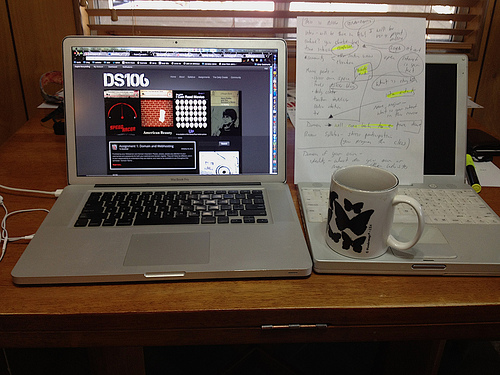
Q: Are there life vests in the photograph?
A: No, there are no life vests.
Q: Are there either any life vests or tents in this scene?
A: No, there are no life vests or tents.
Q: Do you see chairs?
A: No, there are no chairs.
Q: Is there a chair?
A: No, there are no chairs.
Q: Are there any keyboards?
A: Yes, there is a keyboard.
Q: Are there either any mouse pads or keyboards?
A: Yes, there is a keyboard.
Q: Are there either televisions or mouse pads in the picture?
A: No, there are no televisions or mouse pads.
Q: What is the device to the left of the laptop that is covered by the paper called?
A: The device is a keyboard.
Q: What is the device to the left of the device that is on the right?
A: The device is a keyboard.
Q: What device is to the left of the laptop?
A: The device is a keyboard.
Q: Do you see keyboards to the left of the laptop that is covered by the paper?
A: Yes, there is a keyboard to the left of the laptop.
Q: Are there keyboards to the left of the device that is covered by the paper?
A: Yes, there is a keyboard to the left of the laptop.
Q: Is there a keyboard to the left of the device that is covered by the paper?
A: Yes, there is a keyboard to the left of the laptop.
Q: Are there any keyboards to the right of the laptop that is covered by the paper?
A: No, the keyboard is to the left of the laptop.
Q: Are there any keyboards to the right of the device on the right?
A: No, the keyboard is to the left of the laptop.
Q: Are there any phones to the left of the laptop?
A: No, there is a keyboard to the left of the laptop.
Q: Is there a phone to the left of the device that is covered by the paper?
A: No, there is a keyboard to the left of the laptop.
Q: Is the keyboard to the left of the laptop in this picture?
A: Yes, the keyboard is to the left of the laptop.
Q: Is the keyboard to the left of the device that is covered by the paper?
A: Yes, the keyboard is to the left of the laptop.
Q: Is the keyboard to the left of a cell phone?
A: No, the keyboard is to the left of the laptop.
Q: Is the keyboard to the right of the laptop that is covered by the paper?
A: No, the keyboard is to the left of the laptop.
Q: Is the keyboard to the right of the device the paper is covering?
A: No, the keyboard is to the left of the laptop.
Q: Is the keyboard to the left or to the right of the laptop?
A: The keyboard is to the left of the laptop.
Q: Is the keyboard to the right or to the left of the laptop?
A: The keyboard is to the left of the laptop.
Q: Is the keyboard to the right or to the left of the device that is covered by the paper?
A: The keyboard is to the left of the laptop.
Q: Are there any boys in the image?
A: No, there are no boys.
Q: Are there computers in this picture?
A: Yes, there is a computer.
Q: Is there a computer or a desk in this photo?
A: Yes, there is a computer.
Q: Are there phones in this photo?
A: No, there are no phones.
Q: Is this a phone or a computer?
A: This is a computer.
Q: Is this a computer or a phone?
A: This is a computer.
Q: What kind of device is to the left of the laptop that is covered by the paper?
A: The device is a computer.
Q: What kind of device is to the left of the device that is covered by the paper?
A: The device is a computer.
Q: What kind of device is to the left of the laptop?
A: The device is a computer.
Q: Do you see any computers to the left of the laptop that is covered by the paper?
A: Yes, there is a computer to the left of the laptop computer.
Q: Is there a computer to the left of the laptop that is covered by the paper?
A: Yes, there is a computer to the left of the laptop computer.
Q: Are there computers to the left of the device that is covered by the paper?
A: Yes, there is a computer to the left of the laptop computer.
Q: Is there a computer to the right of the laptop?
A: No, the computer is to the left of the laptop.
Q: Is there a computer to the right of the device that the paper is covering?
A: No, the computer is to the left of the laptop.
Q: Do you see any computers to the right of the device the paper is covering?
A: No, the computer is to the left of the laptop.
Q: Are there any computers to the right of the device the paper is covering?
A: No, the computer is to the left of the laptop.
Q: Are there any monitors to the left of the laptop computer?
A: No, there is a computer to the left of the laptop computer.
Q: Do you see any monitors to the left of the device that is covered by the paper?
A: No, there is a computer to the left of the laptop computer.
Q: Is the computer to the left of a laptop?
A: Yes, the computer is to the left of a laptop.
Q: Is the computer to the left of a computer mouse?
A: No, the computer is to the left of a laptop.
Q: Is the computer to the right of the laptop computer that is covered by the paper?
A: No, the computer is to the left of the laptop.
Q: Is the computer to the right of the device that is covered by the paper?
A: No, the computer is to the left of the laptop.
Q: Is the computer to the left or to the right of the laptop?
A: The computer is to the left of the laptop.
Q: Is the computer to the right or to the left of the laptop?
A: The computer is to the left of the laptop.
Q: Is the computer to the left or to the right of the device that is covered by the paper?
A: The computer is to the left of the laptop.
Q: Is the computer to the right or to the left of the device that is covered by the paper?
A: The computer is to the left of the laptop.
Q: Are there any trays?
A: No, there are no trays.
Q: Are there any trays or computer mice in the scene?
A: No, there are no trays or computer mice.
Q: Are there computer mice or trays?
A: No, there are no trays or computer mice.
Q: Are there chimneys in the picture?
A: No, there are no chimneys.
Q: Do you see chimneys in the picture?
A: No, there are no chimneys.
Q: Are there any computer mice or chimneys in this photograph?
A: No, there are no chimneys or computer mice.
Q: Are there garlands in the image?
A: No, there are no garlands.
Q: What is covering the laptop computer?
A: The paper is covering the laptop computer.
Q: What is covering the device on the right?
A: The paper is covering the laptop computer.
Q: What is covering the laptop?
A: The paper is covering the laptop computer.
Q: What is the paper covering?
A: The paper is covering the laptop.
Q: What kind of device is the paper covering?
A: The paper is covering the laptop.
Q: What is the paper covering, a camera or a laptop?
A: The paper is covering a laptop.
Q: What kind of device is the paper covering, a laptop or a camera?
A: The paper is covering a laptop.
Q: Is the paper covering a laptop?
A: Yes, the paper is covering a laptop.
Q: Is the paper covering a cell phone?
A: No, the paper is covering a laptop.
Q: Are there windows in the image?
A: Yes, there is a window.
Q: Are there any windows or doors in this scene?
A: Yes, there is a window.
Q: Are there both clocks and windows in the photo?
A: No, there is a window but no clocks.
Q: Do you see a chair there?
A: No, there are no chairs.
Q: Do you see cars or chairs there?
A: No, there are no chairs or cars.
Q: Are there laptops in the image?
A: Yes, there is a laptop.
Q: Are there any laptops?
A: Yes, there is a laptop.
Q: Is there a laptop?
A: Yes, there is a laptop.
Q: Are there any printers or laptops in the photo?
A: Yes, there is a laptop.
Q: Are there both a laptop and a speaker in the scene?
A: No, there is a laptop but no speakers.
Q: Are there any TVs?
A: No, there are no tvs.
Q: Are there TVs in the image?
A: No, there are no tvs.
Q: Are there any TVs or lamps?
A: No, there are no TVs or lamps.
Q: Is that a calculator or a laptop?
A: That is a laptop.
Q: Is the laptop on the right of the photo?
A: Yes, the laptop is on the right of the image.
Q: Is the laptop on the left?
A: No, the laptop is on the right of the image.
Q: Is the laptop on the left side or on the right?
A: The laptop is on the right of the image.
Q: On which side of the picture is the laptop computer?
A: The laptop computer is on the right of the image.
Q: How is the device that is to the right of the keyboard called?
A: The device is a laptop.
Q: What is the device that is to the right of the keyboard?
A: The device is a laptop.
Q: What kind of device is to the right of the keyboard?
A: The device is a laptop.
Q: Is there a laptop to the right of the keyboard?
A: Yes, there is a laptop to the right of the keyboard.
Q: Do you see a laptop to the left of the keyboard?
A: No, the laptop is to the right of the keyboard.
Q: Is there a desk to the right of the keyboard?
A: No, there is a laptop to the right of the keyboard.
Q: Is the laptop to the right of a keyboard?
A: Yes, the laptop is to the right of a keyboard.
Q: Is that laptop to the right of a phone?
A: No, the laptop is to the right of a keyboard.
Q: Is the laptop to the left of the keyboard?
A: No, the laptop is to the right of the keyboard.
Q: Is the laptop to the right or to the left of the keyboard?
A: The laptop is to the right of the keyboard.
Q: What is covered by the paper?
A: The laptop is covered by the paper.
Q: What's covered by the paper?
A: The laptop is covered by the paper.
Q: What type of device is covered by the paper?
A: The device is a laptop.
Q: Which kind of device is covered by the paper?
A: The device is a laptop.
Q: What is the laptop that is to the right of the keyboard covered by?
A: The laptop is covered by the paper.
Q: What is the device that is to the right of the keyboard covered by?
A: The laptop is covered by the paper.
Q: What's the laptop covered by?
A: The laptop is covered by the paper.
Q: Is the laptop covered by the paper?
A: Yes, the laptop is covered by the paper.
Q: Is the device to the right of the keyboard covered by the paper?
A: Yes, the laptop is covered by the paper.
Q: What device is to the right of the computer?
A: The device is a laptop.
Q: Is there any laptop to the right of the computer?
A: Yes, there is a laptop to the right of the computer.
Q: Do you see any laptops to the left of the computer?
A: No, the laptop is to the right of the computer.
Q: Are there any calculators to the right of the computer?
A: No, there is a laptop to the right of the computer.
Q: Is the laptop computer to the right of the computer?
A: Yes, the laptop computer is to the right of the computer.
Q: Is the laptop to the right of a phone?
A: No, the laptop is to the right of the computer.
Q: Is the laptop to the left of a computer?
A: No, the laptop is to the right of a computer.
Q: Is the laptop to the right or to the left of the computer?
A: The laptop is to the right of the computer.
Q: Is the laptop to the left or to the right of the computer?
A: The laptop is to the right of the computer.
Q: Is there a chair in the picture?
A: No, there are no chairs.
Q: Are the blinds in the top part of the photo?
A: Yes, the blinds are in the top of the image.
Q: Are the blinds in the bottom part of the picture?
A: No, the blinds are in the top of the image.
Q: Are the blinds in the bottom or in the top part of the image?
A: The blinds are in the top of the image.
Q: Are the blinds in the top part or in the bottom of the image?
A: The blinds are in the top of the image.